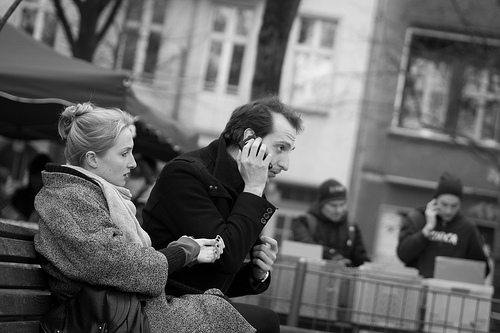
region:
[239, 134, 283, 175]
The phone is black.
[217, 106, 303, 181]
He is talking on the phone.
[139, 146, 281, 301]
The jacket is black.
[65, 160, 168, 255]
She is wearing a scarf.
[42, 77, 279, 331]
They are sitting.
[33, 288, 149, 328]
Her purse is black.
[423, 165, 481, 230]
He is wearing a hat.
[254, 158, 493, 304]
They are standing.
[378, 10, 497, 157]
The tree is bare.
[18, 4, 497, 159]
Windows are on the building.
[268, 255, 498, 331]
a short metal fence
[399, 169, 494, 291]
a man looking at a laptop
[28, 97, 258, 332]
a woman in a coat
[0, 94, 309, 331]
a couple sitting on a bench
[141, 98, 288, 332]
a man talking on the phone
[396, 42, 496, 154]
a pair of windows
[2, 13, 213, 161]
a dark colored awning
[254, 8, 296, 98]
a slightly curved tree trunk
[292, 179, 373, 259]
a man wearing a hat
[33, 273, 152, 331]
a large leather purse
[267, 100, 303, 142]
Caucasian male receding hair line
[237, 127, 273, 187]
mobile phone held up to ear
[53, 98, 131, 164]
long blonde hair tied in ponytail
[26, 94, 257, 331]
woman in elegant clothing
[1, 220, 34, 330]
wooden slats forming bench back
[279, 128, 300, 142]
wrinkled skin on forehead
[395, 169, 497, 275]
person dressed in winter attire talking on mobile phone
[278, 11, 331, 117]
blurred window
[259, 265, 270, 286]
expensive watch worn on wrist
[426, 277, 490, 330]
plastic bin behind fencing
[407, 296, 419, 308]
part of a rail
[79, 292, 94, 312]
part of a sweater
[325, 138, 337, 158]
part of a wall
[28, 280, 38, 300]
back of a bench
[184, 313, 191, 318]
part of a coat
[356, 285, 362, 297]
part of a tank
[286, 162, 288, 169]
nose of a man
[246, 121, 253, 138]
hair of a man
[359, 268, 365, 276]
edge of a tank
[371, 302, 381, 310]
part of a rail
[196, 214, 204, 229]
part of a jacket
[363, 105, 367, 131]
part of a wall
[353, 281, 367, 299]
part of a rail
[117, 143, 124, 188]
face of a woman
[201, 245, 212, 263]
part of a finger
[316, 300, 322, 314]
part of a tank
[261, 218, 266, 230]
part of a button